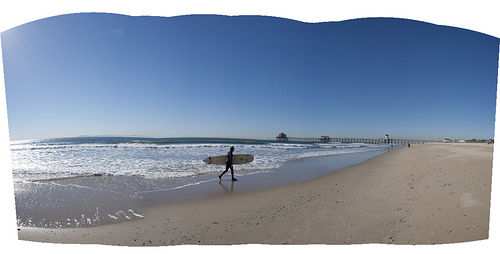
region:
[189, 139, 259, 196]
man walking toward beach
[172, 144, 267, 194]
man carrying surfboard to beach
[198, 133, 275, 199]
man leaving the ocean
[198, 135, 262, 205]
man leaving the water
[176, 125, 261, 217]
man carrying his surfboard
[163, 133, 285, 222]
man with a white surfboard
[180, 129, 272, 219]
surfer finishing his day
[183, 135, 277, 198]
surfer headed toward the sand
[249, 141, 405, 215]
edge of the ocean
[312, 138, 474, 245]
nice sandy beach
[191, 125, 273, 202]
Surfer walking along the beach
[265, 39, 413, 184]
Beach pier behind waves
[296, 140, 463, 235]
Sand along side of beach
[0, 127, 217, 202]
Sun shining on the waves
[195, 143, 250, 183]
Man holding surfboard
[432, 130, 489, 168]
Houses alongside the beach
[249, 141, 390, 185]
Small waves landing ashore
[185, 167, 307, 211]
Feet walking on the sand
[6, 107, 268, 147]
Horizon of a beach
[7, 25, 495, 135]
Blue beach skies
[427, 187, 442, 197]
edge of a shore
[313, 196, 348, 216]
part of a beach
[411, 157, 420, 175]
part of the sand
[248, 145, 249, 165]
tip of a board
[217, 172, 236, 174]
legs of a man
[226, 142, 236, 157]
head of a man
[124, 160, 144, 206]
part of the sea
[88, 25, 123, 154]
part of a water wave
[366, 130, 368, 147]
part of the ocean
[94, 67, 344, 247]
the beach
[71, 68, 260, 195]
the beach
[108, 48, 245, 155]
the beach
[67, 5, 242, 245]
the beach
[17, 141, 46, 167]
reflection of sun on water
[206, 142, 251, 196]
surfer walking in water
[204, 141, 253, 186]
surfer walking in water toward beach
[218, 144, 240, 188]
surfer wearing black wet suit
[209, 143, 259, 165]
surfer carrying long surf board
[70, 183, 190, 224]
tan and brown wet sand at beach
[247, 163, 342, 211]
tan and brown wet sand at beach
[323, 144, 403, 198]
tan and brown wet sand at beach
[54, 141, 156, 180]
white foam of blue ocean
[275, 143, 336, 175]
white foam of blue ocean